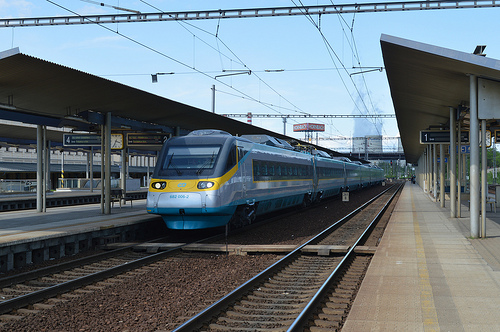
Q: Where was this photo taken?
A: Train station.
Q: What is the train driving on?
A: Train tracks.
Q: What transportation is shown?
A: Train.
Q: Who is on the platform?
A: No body.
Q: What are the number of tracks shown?
A: 2.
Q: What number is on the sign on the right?
A: 1.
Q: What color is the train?
A: Light blue, white and yellow stripes.